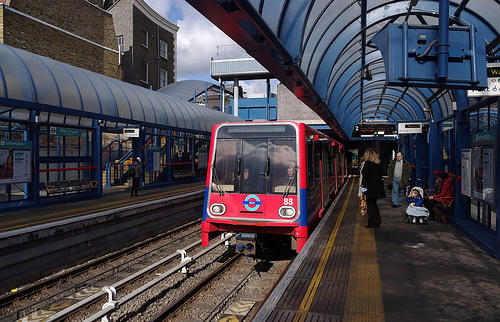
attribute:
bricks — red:
[260, 175, 357, 320]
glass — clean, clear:
[12, 50, 221, 132]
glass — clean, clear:
[2, 40, 252, 137]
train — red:
[203, 119, 351, 248]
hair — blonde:
[361, 145, 381, 166]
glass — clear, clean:
[214, 124, 296, 194]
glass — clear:
[129, 114, 308, 198]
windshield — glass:
[214, 135, 299, 192]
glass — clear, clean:
[44, 53, 84, 110]